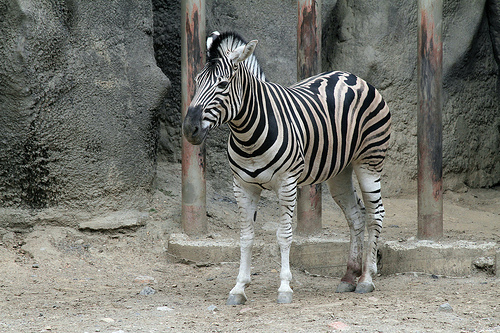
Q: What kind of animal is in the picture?
A: A zebra.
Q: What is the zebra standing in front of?
A: Metal bars.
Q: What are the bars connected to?
A: Stone base.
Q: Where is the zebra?
A: In a zoo.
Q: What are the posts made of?
A: Metal.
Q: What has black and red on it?
A: Part of the post.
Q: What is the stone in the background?
A: The wall.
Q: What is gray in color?
A: The wall.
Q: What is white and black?
A: The zebra.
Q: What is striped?
A: The zebra.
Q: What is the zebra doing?
A: Standing.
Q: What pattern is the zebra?
A: Striped.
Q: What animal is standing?
A: Zebra.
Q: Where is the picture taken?
A: Zoo.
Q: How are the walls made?
A: Of stone.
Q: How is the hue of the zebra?
A: Black and white.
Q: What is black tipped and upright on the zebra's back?
A: Mane.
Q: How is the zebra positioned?
A: Upright.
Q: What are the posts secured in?
A: Concrete.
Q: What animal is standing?
A: Zebra.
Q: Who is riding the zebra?
A: No one.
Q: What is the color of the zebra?
A: Black and white.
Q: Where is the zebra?
A: At the zoo.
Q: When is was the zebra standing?
A: Daytime.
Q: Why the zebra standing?
A: To rest.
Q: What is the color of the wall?
A: Gray.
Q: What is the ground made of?
A: Sand, stone and soil.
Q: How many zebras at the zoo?
A: One.